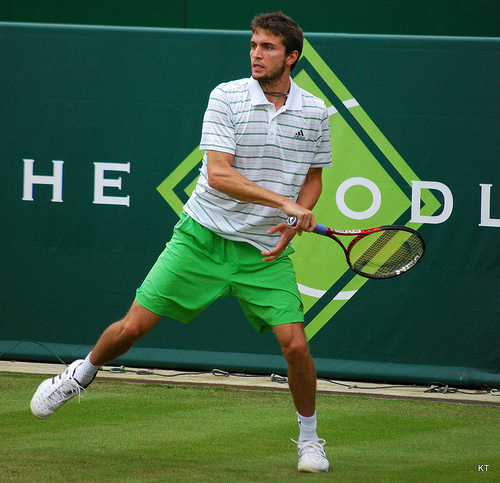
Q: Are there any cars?
A: No, there are no cars.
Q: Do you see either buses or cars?
A: No, there are no cars or buses.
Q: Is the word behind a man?
A: Yes, the word is behind a man.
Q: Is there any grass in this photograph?
A: Yes, there is grass.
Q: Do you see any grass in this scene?
A: Yes, there is grass.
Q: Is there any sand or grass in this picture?
A: Yes, there is grass.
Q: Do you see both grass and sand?
A: No, there is grass but no sand.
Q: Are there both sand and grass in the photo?
A: No, there is grass but no sand.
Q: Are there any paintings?
A: No, there are no paintings.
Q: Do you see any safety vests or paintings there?
A: No, there are no paintings or safety vests.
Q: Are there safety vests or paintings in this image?
A: No, there are no paintings or safety vests.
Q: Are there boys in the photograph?
A: No, there are no boys.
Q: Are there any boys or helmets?
A: No, there are no boys or helmets.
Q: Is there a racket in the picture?
A: Yes, there is a racket.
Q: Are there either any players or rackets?
A: Yes, there is a racket.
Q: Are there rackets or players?
A: Yes, there is a racket.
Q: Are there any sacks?
A: No, there are no sacks.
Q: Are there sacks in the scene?
A: No, there are no sacks.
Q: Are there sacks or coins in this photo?
A: No, there are no sacks or coins.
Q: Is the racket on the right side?
A: Yes, the racket is on the right of the image.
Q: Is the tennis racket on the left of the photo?
A: No, the tennis racket is on the right of the image.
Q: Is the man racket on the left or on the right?
A: The racket is on the right of the image.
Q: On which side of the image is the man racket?
A: The racket is on the right of the image.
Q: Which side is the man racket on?
A: The racket is on the right of the image.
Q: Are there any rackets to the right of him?
A: Yes, there is a racket to the right of the man.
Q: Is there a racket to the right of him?
A: Yes, there is a racket to the right of the man.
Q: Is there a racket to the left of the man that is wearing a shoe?
A: No, the racket is to the right of the man.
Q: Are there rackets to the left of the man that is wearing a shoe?
A: No, the racket is to the right of the man.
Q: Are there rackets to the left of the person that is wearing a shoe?
A: No, the racket is to the right of the man.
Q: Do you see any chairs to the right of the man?
A: No, there is a racket to the right of the man.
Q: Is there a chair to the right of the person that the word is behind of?
A: No, there is a racket to the right of the man.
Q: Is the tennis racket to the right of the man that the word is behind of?
A: Yes, the tennis racket is to the right of the man.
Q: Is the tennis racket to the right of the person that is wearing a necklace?
A: Yes, the tennis racket is to the right of the man.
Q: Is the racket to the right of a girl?
A: No, the racket is to the right of the man.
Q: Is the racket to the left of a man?
A: No, the racket is to the right of a man.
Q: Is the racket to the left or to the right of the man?
A: The racket is to the right of the man.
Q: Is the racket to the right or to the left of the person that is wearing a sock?
A: The racket is to the right of the man.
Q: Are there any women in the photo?
A: No, there are no women.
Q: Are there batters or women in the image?
A: No, there are no women or batters.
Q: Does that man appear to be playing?
A: Yes, the man is playing.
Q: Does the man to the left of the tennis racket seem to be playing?
A: Yes, the man is playing.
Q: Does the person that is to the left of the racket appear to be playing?
A: Yes, the man is playing.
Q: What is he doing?
A: The man is playing.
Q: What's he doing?
A: The man is playing.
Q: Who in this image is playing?
A: The man is playing.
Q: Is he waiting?
A: No, the man is playing.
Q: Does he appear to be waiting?
A: No, the man is playing.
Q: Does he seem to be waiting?
A: No, the man is playing.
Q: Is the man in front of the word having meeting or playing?
A: The man is playing.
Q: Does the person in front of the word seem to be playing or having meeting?
A: The man is playing.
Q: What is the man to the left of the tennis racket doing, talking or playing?
A: The man is playing.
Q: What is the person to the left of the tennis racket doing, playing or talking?
A: The man is playing.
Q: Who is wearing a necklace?
A: The man is wearing a necklace.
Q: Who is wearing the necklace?
A: The man is wearing a necklace.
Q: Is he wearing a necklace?
A: Yes, the man is wearing a necklace.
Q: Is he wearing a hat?
A: No, the man is wearing a necklace.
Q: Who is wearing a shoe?
A: The man is wearing a shoe.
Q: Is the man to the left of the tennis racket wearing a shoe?
A: Yes, the man is wearing a shoe.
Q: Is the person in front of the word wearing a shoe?
A: Yes, the man is wearing a shoe.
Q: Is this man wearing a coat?
A: No, the man is wearing a shoe.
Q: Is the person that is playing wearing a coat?
A: No, the man is wearing a shoe.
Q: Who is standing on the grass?
A: The man is standing on the grass.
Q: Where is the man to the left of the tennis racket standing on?
A: The man is standing on the grass.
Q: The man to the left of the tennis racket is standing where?
A: The man is standing on the grass.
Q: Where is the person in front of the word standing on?
A: The man is standing on the grass.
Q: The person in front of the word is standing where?
A: The man is standing on the grass.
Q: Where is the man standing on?
A: The man is standing on the grass.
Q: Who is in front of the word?
A: The man is in front of the word.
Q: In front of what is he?
A: The man is in front of the word.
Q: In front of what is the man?
A: The man is in front of the word.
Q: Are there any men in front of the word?
A: Yes, there is a man in front of the word.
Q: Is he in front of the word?
A: Yes, the man is in front of the word.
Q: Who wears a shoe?
A: The man wears a shoe.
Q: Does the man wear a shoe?
A: Yes, the man wears a shoe.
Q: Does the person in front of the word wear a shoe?
A: Yes, the man wears a shoe.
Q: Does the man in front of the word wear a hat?
A: No, the man wears a shoe.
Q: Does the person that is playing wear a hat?
A: No, the man wears a shoe.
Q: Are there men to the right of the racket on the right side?
A: No, the man is to the left of the racket.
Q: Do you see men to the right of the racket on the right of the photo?
A: No, the man is to the left of the racket.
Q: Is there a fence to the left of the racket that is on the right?
A: No, there is a man to the left of the racket.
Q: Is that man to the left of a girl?
A: No, the man is to the left of the racket.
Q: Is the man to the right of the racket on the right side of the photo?
A: No, the man is to the left of the racket.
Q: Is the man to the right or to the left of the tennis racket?
A: The man is to the left of the tennis racket.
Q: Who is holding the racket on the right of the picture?
A: The man is holding the racket.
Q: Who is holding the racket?
A: The man is holding the racket.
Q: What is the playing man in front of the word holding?
A: The man is holding the tennis racket.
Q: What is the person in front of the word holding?
A: The man is holding the tennis racket.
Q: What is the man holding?
A: The man is holding the tennis racket.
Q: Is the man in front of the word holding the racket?
A: Yes, the man is holding the racket.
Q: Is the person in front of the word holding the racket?
A: Yes, the man is holding the racket.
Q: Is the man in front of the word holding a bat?
A: No, the man is holding the racket.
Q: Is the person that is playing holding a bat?
A: No, the man is holding the racket.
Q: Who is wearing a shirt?
A: The man is wearing a shirt.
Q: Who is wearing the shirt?
A: The man is wearing a shirt.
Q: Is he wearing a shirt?
A: Yes, the man is wearing a shirt.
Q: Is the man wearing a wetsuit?
A: No, the man is wearing a shirt.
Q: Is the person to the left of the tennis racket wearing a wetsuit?
A: No, the man is wearing a shirt.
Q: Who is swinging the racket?
A: The man is swinging the racket.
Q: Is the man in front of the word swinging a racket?
A: Yes, the man is swinging a racket.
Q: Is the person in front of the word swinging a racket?
A: Yes, the man is swinging a racket.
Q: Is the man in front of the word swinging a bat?
A: No, the man is swinging a racket.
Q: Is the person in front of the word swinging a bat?
A: No, the man is swinging a racket.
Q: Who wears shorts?
A: The man wears shorts.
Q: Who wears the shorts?
A: The man wears shorts.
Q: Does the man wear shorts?
A: Yes, the man wears shorts.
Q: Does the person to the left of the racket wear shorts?
A: Yes, the man wears shorts.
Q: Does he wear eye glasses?
A: No, the man wears shorts.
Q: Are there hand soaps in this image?
A: No, there are no hand soaps.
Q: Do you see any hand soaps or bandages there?
A: No, there are no hand soaps or bandages.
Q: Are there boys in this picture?
A: No, there are no boys.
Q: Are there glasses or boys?
A: No, there are no boys or glasses.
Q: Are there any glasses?
A: No, there are no glasses.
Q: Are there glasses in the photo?
A: No, there are no glasses.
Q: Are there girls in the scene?
A: No, there are no girls.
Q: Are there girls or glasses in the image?
A: No, there are no girls or glasses.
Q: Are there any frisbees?
A: No, there are no frisbees.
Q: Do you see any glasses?
A: No, there are no glasses.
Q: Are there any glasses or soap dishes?
A: No, there are no glasses or soap dishes.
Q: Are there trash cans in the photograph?
A: No, there are no trash cans.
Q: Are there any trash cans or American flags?
A: No, there are no trash cans or American flags.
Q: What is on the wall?
A: The letter is on the wall.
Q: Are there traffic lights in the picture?
A: No, there are no traffic lights.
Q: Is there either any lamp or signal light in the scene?
A: No, there are no traffic lights or lamps.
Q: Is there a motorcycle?
A: No, there are no motorcycles.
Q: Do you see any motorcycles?
A: No, there are no motorcycles.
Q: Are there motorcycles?
A: No, there are no motorcycles.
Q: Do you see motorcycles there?
A: No, there are no motorcycles.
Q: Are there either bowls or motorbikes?
A: No, there are no motorbikes or bowls.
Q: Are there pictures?
A: No, there are no pictures.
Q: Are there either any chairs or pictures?
A: No, there are no pictures or chairs.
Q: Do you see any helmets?
A: No, there are no helmets.